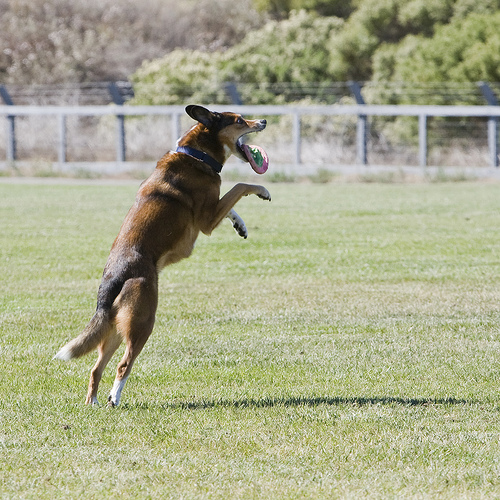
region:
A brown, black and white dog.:
[48, 86, 313, 437]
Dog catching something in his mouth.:
[56, 101, 302, 421]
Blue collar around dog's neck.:
[161, 131, 233, 173]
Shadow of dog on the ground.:
[172, 383, 475, 415]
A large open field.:
[17, 173, 490, 497]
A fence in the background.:
[5, 73, 499, 175]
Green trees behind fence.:
[119, 0, 493, 106]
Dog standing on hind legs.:
[73, 89, 288, 418]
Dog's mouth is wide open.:
[186, 94, 281, 181]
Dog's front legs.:
[194, 167, 274, 246]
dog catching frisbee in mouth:
[189, 93, 274, 177]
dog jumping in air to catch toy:
[49, 95, 291, 427]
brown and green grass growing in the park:
[343, 228, 469, 355]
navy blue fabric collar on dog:
[171, 135, 225, 177]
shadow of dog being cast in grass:
[146, 367, 488, 435]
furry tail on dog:
[50, 310, 115, 372]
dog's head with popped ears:
[178, 100, 273, 178]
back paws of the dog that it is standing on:
[61, 370, 143, 419]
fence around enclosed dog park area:
[299, 68, 447, 188]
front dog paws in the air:
[225, 175, 281, 252]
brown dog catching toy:
[52, 93, 262, 391]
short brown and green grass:
[41, 402, 115, 476]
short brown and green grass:
[191, 403, 301, 487]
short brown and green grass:
[302, 408, 379, 478]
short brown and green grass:
[391, 343, 483, 466]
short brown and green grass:
[193, 317, 280, 426]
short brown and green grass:
[278, 241, 396, 391]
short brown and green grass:
[375, 207, 465, 300]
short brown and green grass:
[35, 188, 89, 249]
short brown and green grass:
[289, 184, 347, 260]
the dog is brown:
[49, 55, 265, 392]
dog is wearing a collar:
[167, 140, 242, 195]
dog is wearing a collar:
[164, 134, 226, 176]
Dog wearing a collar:
[170, 141, 226, 173]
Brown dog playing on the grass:
[51, 100, 271, 411]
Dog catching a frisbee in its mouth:
[240, 135, 270, 175]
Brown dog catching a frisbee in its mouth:
[240, 140, 270, 175]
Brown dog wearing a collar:
[173, 140, 225, 174]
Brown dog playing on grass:
[54, 100, 271, 410]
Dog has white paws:
[228, 182, 272, 239]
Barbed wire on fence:
[1, 76, 496, 107]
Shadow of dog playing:
[111, 390, 491, 410]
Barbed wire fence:
[0, 76, 497, 177]